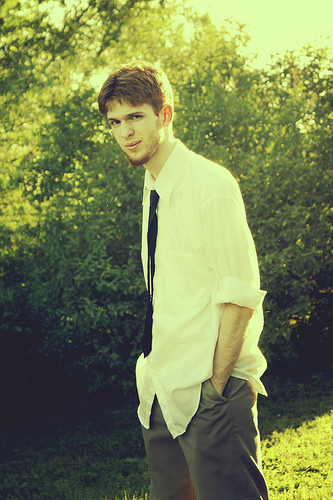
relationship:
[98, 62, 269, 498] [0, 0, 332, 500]
guy standing in garden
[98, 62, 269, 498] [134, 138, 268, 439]
guy wearing t-shirt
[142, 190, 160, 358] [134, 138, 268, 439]
tie on top of t-shirt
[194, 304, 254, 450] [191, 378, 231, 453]
hands inside of pockets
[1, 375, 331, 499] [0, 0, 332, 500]
grass inside a garden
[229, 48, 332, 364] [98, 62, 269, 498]
bush behind guy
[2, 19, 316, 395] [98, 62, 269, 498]
bush behind guy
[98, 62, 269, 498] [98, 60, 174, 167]
guy has head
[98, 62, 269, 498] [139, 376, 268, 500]
guy wearing pants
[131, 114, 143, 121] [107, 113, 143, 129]
eye has intense look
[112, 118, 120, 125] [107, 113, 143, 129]
eye has intense look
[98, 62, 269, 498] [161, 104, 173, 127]
guy has ear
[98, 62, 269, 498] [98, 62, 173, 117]
guy has hair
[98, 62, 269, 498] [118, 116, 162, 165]
guy has beard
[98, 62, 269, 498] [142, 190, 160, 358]
guy wearing tie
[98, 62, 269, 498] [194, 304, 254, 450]
guy has hands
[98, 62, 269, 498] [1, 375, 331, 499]
guy walking on grass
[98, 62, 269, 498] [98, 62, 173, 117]
guy has orange hair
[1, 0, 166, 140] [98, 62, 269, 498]
tree behind guy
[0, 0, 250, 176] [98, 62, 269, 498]
tree behind guy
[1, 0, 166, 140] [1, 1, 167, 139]
tree has leaves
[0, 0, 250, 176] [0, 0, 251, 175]
tree has leaves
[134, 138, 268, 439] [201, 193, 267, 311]
t-shirt has sleeve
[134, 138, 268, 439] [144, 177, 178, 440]
t-shirt has buttons